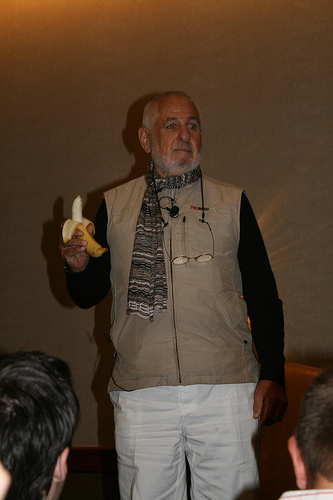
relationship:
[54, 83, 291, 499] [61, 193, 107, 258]
man standing with banana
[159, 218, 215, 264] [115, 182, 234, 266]
glasses resting on chest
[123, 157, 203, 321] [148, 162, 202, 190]
scarf around neck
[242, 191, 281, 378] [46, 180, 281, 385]
slleves of man shirt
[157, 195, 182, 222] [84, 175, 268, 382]
microphone clipped to jacket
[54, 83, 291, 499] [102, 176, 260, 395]
man wearing jacket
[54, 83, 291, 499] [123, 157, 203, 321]
man wearing scarf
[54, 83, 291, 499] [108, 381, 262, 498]
man wearing pants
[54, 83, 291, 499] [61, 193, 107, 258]
man holding banana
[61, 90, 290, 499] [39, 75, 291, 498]
man holds banana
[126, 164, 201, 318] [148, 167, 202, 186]
scarf on neck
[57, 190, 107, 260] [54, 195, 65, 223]
banana has shadow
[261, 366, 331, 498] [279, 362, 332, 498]
man has head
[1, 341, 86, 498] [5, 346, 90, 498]
man has head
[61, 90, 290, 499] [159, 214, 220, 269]
man has glasses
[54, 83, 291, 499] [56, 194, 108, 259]
man holds banana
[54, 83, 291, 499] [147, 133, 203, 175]
man has facial hair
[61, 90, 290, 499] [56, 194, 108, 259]
man holding banana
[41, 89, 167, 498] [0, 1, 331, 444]
shadow of man and banana on wall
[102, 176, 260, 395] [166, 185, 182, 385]
jacket with front zipper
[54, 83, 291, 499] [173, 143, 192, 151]
man has moustache